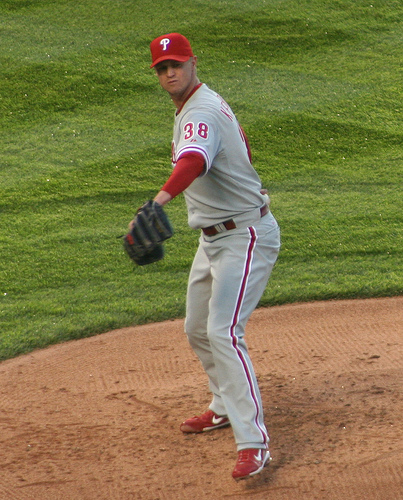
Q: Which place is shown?
A: It is a field.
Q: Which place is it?
A: It is a field.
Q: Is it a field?
A: Yes, it is a field.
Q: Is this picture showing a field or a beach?
A: It is showing a field.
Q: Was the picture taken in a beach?
A: No, the picture was taken in a field.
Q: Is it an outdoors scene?
A: Yes, it is outdoors.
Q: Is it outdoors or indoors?
A: It is outdoors.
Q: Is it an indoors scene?
A: No, it is outdoors.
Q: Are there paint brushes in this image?
A: No, there are no paint brushes.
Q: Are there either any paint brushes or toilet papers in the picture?
A: No, there are no paint brushes or toilet papers.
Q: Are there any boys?
A: No, there are no boys.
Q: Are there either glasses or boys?
A: No, there are no boys or glasses.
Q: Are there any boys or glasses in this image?
A: No, there are no boys or glasses.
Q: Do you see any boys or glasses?
A: No, there are no boys or glasses.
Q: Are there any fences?
A: No, there are no fences.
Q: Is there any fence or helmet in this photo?
A: No, there are no fences or helmets.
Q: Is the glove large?
A: Yes, the glove is large.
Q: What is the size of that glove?
A: The glove is large.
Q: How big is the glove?
A: The glove is large.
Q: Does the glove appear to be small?
A: No, the glove is large.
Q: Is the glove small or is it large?
A: The glove is large.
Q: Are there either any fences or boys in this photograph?
A: No, there are no boys or fences.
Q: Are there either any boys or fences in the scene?
A: No, there are no boys or fences.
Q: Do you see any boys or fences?
A: No, there are no boys or fences.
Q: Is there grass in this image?
A: Yes, there is grass.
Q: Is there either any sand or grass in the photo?
A: Yes, there is grass.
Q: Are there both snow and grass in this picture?
A: No, there is grass but no snow.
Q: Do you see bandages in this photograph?
A: No, there are no bandages.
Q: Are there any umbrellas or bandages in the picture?
A: No, there are no bandages or umbrellas.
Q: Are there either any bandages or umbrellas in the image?
A: No, there are no bandages or umbrellas.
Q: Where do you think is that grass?
A: The grass is in the field.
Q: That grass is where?
A: The grass is in the field.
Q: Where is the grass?
A: The grass is in the field.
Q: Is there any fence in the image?
A: No, there are no fences.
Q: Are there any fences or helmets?
A: No, there are no fences or helmets.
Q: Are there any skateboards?
A: No, there are no skateboards.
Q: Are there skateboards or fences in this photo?
A: No, there are no skateboards or fences.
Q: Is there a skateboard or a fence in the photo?
A: No, there are no skateboards or fences.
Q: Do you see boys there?
A: No, there are no boys.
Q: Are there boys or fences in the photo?
A: No, there are no boys or fences.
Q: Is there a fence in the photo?
A: No, there are no fences.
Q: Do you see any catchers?
A: No, there are no catchers.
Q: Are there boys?
A: No, there are no boys.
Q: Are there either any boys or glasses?
A: No, there are no boys or glasses.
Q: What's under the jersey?
A: The shirt is under the jersey.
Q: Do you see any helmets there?
A: No, there are no helmets.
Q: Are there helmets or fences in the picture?
A: No, there are no helmets or fences.